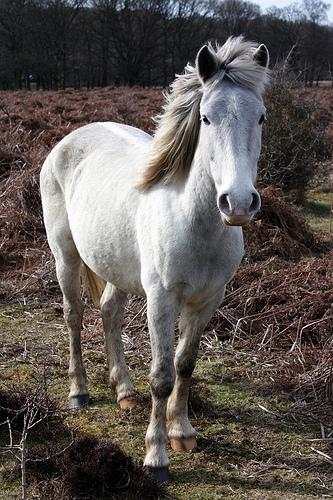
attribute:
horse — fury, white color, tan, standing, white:
[37, 36, 268, 477]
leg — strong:
[140, 266, 176, 476]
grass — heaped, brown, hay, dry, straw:
[1, 79, 332, 498]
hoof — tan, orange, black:
[169, 438, 198, 455]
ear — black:
[197, 47, 219, 80]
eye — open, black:
[258, 115, 266, 127]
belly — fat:
[70, 198, 143, 299]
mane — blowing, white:
[139, 35, 274, 192]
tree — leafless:
[108, 3, 167, 84]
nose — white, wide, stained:
[224, 205, 254, 227]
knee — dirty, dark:
[151, 368, 174, 400]